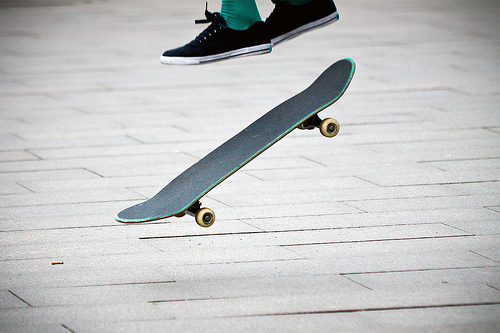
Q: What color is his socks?
A: Green.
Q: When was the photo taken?
A: Day time.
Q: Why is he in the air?
A: He Is jumping.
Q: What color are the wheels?
A: White.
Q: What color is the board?
A: Black.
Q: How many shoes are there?
A: Two.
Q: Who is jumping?
A: Skater.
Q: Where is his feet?
A: In the air.